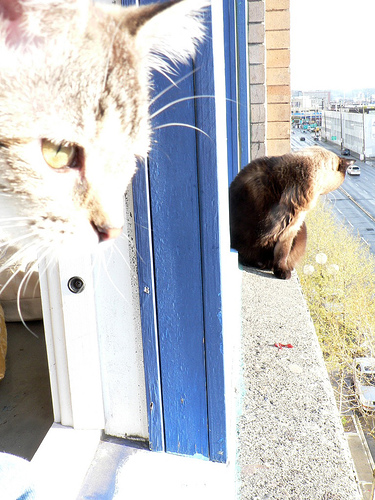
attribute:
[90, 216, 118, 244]
nose — cat's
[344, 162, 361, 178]
car — white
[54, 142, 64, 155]
pupil — thin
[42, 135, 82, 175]
eye — green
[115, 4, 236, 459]
paint — is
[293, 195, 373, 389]
grass — yellow